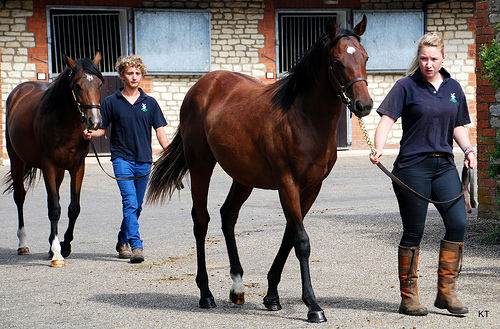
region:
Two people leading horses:
[2, 13, 472, 317]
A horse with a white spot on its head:
[149, 12, 373, 322]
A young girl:
[372, 19, 475, 316]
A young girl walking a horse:
[152, 14, 476, 322]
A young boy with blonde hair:
[84, 55, 167, 263]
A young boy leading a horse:
[5, 50, 161, 265]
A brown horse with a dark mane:
[5, 52, 104, 267]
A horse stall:
[45, 5, 130, 154]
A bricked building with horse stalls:
[0, 0, 476, 150]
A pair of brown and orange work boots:
[399, 240, 468, 317]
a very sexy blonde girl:
[391, 39, 478, 304]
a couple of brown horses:
[10, 58, 369, 283]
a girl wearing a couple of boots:
[394, 237, 471, 315]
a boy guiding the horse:
[113, 60, 157, 263]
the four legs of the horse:
[191, 177, 328, 320]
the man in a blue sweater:
[106, 64, 160, 163]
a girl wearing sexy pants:
[390, 152, 470, 238]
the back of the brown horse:
[193, 60, 279, 95]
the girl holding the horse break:
[338, 73, 375, 115]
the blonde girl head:
[411, 30, 443, 76]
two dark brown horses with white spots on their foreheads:
[5, 14, 376, 326]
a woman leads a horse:
[370, 29, 482, 315]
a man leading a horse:
[80, 48, 173, 266]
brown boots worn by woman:
[389, 236, 476, 318]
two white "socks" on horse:
[7, 221, 79, 269]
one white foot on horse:
[222, 269, 254, 310]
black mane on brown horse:
[253, 13, 365, 117]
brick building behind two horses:
[0, 0, 497, 225]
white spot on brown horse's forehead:
[342, 40, 362, 60]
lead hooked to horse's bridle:
[339, 88, 485, 215]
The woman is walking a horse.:
[147, 5, 492, 324]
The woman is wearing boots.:
[370, 23, 485, 326]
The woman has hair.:
[378, 28, 486, 178]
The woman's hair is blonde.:
[368, 24, 483, 185]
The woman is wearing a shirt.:
[372, 33, 484, 176]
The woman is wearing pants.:
[364, 30, 484, 325]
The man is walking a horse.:
[1, 37, 188, 271]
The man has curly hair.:
[106, 47, 152, 132]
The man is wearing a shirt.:
[94, 44, 173, 168]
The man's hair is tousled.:
[102, 45, 159, 112]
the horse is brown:
[171, 33, 384, 223]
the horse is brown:
[13, 50, 131, 249]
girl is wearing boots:
[356, 212, 466, 323]